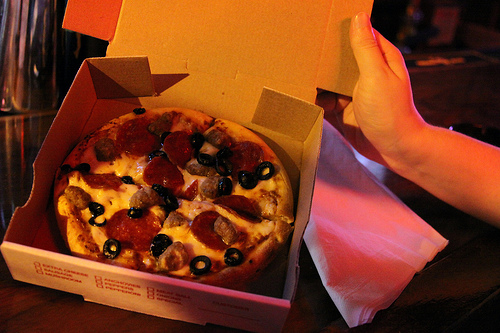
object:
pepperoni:
[117, 114, 154, 156]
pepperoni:
[162, 127, 190, 163]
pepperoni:
[233, 140, 259, 168]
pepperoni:
[146, 160, 184, 187]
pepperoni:
[184, 179, 197, 201]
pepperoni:
[80, 174, 122, 189]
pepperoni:
[190, 212, 215, 246]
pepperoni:
[110, 210, 152, 248]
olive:
[134, 121, 167, 137]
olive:
[192, 135, 205, 144]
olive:
[198, 156, 216, 171]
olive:
[219, 164, 233, 176]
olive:
[237, 172, 251, 184]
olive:
[258, 164, 273, 180]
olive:
[215, 181, 229, 196]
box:
[0, 50, 332, 314]